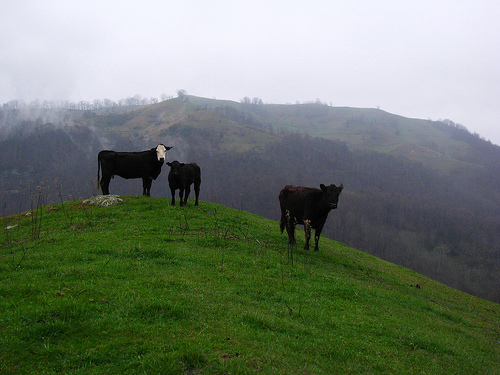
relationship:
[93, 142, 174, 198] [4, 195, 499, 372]
cow standing on mountain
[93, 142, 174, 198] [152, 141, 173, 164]
cow has face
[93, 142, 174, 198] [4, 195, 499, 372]
cow on hill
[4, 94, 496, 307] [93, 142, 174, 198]
mountain behind cow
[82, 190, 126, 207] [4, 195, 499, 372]
rock on mountain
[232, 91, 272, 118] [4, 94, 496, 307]
tree in mountain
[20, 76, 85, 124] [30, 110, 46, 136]
fog coming from tree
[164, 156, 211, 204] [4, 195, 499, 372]
cow on mountain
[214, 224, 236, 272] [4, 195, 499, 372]
stick coming out mountain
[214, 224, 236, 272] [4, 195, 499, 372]
stick jutting out mountain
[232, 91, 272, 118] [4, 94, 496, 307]
tree on top of mountain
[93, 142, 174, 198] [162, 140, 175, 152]
cow has ear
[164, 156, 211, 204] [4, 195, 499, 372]
cow standing on top of mountain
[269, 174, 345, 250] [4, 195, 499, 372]
cow standing on mountain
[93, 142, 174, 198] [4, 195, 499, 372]
cow standing on top of mountain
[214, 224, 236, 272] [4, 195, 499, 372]
stick on top of mountain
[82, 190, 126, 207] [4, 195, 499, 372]
rock on top of mountain